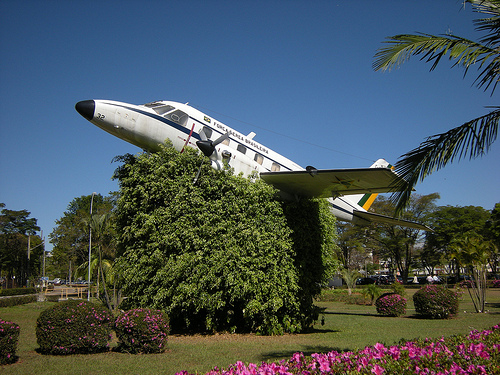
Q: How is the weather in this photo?
A: It is clear.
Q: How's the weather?
A: It is clear.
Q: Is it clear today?
A: Yes, it is clear.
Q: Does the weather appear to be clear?
A: Yes, it is clear.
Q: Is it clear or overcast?
A: It is clear.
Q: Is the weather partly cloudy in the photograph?
A: No, it is clear.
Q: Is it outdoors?
A: Yes, it is outdoors.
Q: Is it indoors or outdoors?
A: It is outdoors.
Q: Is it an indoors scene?
A: No, it is outdoors.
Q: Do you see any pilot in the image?
A: No, there are no pilots.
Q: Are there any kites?
A: No, there are no kites.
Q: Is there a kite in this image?
A: No, there are no kites.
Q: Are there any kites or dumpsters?
A: No, there are no kites or dumpsters.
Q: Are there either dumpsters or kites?
A: No, there are no kites or dumpsters.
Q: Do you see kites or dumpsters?
A: No, there are no kites or dumpsters.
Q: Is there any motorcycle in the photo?
A: No, there are no motorcycles.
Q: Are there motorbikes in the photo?
A: No, there are no motorbikes.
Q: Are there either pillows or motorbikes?
A: No, there are no motorbikes or pillows.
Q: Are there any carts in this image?
A: No, there are no carts.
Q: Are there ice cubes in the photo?
A: No, there are no ice cubes.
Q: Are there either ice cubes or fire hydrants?
A: No, there are no ice cubes or fire hydrants.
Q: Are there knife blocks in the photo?
A: No, there are no knife blocks.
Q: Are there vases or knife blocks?
A: No, there are no knife blocks or vases.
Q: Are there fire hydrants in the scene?
A: No, there are no fire hydrants.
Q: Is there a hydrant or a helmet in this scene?
A: No, there are no fire hydrants or helmets.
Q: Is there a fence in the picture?
A: No, there are no fences.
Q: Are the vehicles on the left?
A: Yes, the vehicles are on the left of the image.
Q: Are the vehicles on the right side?
A: No, the vehicles are on the left of the image.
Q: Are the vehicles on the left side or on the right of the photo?
A: The vehicles are on the left of the image.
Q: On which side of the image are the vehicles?
A: The vehicles are on the left of the image.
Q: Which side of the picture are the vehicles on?
A: The vehicles are on the left of the image.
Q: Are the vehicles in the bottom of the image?
A: Yes, the vehicles are in the bottom of the image.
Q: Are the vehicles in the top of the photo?
A: No, the vehicles are in the bottom of the image.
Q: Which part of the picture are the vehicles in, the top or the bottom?
A: The vehicles are in the bottom of the image.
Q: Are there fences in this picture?
A: No, there are no fences.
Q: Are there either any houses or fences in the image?
A: No, there are no fences or houses.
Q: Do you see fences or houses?
A: No, there are no fences or houses.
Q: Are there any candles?
A: No, there are no candles.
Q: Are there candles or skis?
A: No, there are no candles or skis.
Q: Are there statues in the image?
A: No, there are no statues.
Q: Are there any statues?
A: No, there are no statues.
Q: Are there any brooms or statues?
A: No, there are no statues or brooms.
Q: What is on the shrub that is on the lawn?
A: The flowers are on the bush.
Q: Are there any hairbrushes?
A: No, there are no hairbrushes.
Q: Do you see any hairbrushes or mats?
A: No, there are no hairbrushes or mats.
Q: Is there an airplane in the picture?
A: Yes, there is an airplane.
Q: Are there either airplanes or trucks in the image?
A: Yes, there is an airplane.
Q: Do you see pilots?
A: No, there are no pilots.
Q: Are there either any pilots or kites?
A: No, there are no pilots or kites.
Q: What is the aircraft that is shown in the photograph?
A: The aircraft is an airplane.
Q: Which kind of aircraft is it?
A: The aircraft is an airplane.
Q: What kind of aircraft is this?
A: This is an airplane.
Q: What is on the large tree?
A: The airplane is on the tree.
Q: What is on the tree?
A: The airplane is on the tree.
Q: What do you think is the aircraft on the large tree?
A: The aircraft is an airplane.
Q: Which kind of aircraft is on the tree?
A: The aircraft is an airplane.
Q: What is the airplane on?
A: The airplane is on the tree.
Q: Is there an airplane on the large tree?
A: Yes, there is an airplane on the tree.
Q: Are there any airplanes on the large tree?
A: Yes, there is an airplane on the tree.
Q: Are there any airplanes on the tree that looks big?
A: Yes, there is an airplane on the tree.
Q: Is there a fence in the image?
A: No, there are no fences.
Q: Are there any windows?
A: Yes, there are windows.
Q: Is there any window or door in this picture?
A: Yes, there are windows.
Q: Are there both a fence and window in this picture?
A: No, there are windows but no fences.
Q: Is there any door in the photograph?
A: No, there are no doors.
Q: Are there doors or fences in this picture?
A: No, there are no doors or fences.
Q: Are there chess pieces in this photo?
A: No, there are no chess pieces.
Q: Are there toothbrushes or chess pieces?
A: No, there are no chess pieces or toothbrushes.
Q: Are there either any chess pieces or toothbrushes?
A: No, there are no chess pieces or toothbrushes.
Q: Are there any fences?
A: No, there are no fences.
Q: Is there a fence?
A: No, there are no fences.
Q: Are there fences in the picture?
A: No, there are no fences.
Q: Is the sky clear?
A: Yes, the sky is clear.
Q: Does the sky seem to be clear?
A: Yes, the sky is clear.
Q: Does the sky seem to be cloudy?
A: No, the sky is clear.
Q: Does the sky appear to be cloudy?
A: No, the sky is clear.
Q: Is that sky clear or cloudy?
A: The sky is clear.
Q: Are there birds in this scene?
A: No, there are no birds.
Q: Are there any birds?
A: No, there are no birds.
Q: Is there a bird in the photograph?
A: No, there are no birds.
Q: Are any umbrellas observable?
A: No, there are no umbrellas.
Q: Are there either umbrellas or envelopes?
A: No, there are no umbrellas or envelopes.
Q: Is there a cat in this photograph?
A: No, there are no cats.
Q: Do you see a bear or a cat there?
A: No, there are no cats or bears.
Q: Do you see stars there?
A: Yes, there is a star.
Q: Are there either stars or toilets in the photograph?
A: Yes, there is a star.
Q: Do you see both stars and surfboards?
A: No, there is a star but no surfboards.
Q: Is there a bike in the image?
A: No, there are no bikes.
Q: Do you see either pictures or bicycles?
A: No, there are no bicycles or pictures.